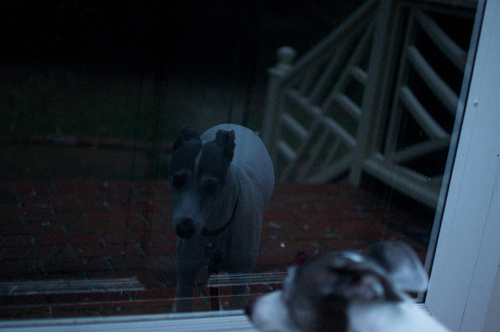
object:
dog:
[236, 227, 459, 332]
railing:
[251, 0, 491, 216]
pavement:
[0, 177, 407, 322]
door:
[350, 1, 500, 305]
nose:
[178, 215, 196, 229]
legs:
[218, 257, 259, 316]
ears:
[208, 126, 239, 165]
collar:
[197, 219, 233, 240]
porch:
[45, 233, 130, 269]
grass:
[82, 87, 128, 118]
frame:
[382, 0, 486, 107]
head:
[161, 122, 239, 242]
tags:
[202, 236, 222, 262]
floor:
[25, 178, 89, 222]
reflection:
[0, 0, 500, 329]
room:
[0, 0, 500, 332]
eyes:
[199, 178, 223, 196]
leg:
[167, 237, 216, 323]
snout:
[183, 219, 192, 224]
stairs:
[270, 99, 355, 161]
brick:
[28, 225, 114, 250]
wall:
[0, 0, 396, 78]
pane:
[418, 10, 475, 53]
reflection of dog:
[156, 118, 286, 319]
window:
[0, 0, 492, 327]